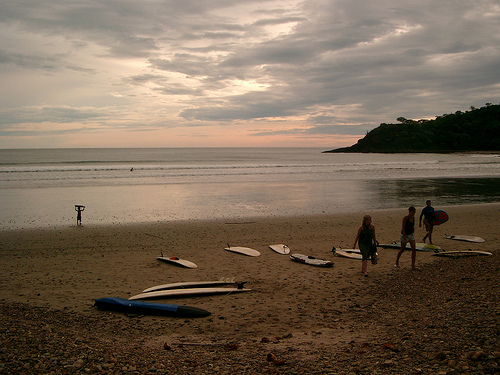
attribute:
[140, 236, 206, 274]
surfboard — white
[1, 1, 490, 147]
sky — cloudy, light red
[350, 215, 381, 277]
man — walking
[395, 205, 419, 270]
woman — walking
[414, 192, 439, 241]
person — walking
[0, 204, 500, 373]
sand — brown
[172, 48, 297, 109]
clouds — white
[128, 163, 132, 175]
person — surfing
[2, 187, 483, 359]
sand — wet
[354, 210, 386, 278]
person — walking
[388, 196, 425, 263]
person — walking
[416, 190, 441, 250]
person — walking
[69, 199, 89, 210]
board — overhead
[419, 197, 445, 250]
man — walking